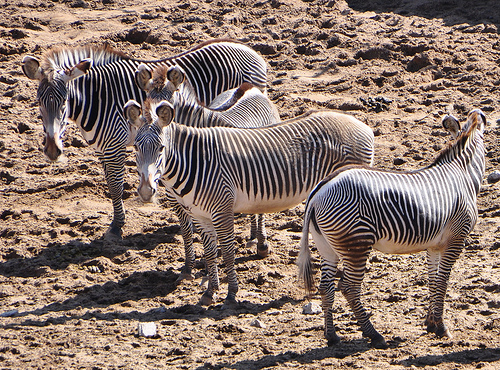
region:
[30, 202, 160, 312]
shadows on the ground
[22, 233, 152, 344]
shadows on the ground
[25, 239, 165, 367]
shadows on the ground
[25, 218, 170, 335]
shadows on the ground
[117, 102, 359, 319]
black and white stripes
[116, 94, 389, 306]
black and white stripes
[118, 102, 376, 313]
black and white stripes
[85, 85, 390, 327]
black and white stripes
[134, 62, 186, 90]
Ears of the next to furthest zebra.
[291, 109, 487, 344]
Zebra turned around facing right.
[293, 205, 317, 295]
Black and white tail of the right facing zebra.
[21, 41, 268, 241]
The largest zebra looking this way.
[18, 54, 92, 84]
Two brown, black and white ears on the largest zebra.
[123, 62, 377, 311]
The two middle black and white zebras.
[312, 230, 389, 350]
Black and white legs of a zebra facing right.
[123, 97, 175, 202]
Black and white head of a zebra fully visible and light in color.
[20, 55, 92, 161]
Large ears and darker black and white face of a large zebra.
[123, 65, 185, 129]
Two sets of middle zebra ears.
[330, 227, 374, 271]
dirt on side of zebra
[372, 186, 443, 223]
pattern o side of zebra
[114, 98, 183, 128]
large ears of zebra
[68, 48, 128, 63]
white and brown hair on zebra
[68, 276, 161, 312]
foot prints in sand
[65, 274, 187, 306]
shadow in sand from zebra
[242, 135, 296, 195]
straight pattern on side of zebra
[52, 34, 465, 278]
four zebras standing side by side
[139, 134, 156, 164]
pattern on head of zebra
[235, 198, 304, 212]
white belly of zebra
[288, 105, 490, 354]
Zebra is standing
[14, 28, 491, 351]
Zebras are standing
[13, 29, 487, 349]
Group of zebras standing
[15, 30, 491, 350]
Group of zebras are standing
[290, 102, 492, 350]
Zebra standing in the dirt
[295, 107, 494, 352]
Zebra is standing in the dirt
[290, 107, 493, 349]
Zebra standing on the dirt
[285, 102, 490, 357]
Zebra is standing on the dirt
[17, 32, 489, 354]
Zebras standing in the dirt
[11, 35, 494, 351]
Zebras are standing on the dirt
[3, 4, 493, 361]
four zebras on a field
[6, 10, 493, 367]
field is cover with soil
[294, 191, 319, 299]
long tail of zebra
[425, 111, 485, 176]
mane with brown border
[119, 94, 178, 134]
two long ears of zebra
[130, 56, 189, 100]
two long ears of zebra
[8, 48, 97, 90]
two long ears of zebra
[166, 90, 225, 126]
black and white mane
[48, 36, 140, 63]
black and white mane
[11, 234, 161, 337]
shadows cast on the ground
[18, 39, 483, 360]
Four zebras standing around.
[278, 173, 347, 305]
The tail of a zebra.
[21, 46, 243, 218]
Three zebras looking at the camera.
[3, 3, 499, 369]
Packed tan dirt all around.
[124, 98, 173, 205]
A zebras face with white at the nose.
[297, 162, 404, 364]
A zebras back end.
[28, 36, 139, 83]
A zebras mane standing up straight.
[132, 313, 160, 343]
A white rock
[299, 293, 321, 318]
A white rock close to a zebra.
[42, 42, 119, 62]
black and white mane on zebra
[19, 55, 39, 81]
white ear on zebra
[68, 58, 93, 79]
white ear on zebra